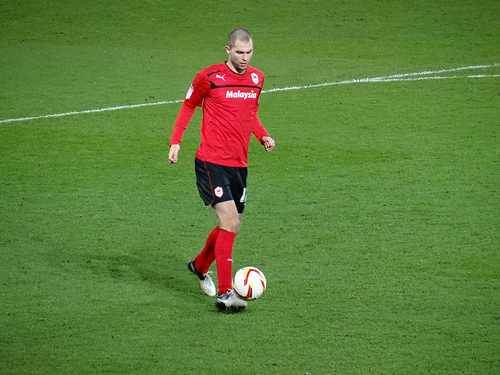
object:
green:
[104, 20, 423, 269]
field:
[307, 74, 403, 208]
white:
[0, 111, 81, 122]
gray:
[216, 291, 246, 306]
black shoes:
[188, 259, 248, 311]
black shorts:
[195, 157, 248, 213]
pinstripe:
[203, 160, 215, 206]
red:
[168, 62, 268, 169]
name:
[226, 89, 257, 99]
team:
[226, 90, 257, 100]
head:
[225, 28, 254, 69]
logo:
[214, 186, 224, 197]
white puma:
[225, 91, 257, 100]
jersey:
[170, 62, 268, 169]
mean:
[169, 62, 273, 168]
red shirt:
[168, 61, 270, 168]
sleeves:
[168, 70, 208, 146]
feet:
[187, 260, 247, 309]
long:
[194, 225, 236, 297]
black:
[189, 259, 205, 280]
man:
[168, 28, 273, 311]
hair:
[227, 28, 250, 49]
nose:
[243, 56, 249, 62]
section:
[316, 80, 419, 162]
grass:
[310, 7, 407, 108]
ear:
[225, 46, 230, 55]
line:
[0, 63, 500, 124]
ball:
[232, 267, 266, 300]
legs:
[197, 189, 240, 288]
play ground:
[0, 0, 500, 375]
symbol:
[214, 187, 224, 198]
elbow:
[181, 97, 196, 111]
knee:
[217, 212, 240, 232]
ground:
[0, 0, 500, 375]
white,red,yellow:
[244, 268, 261, 286]